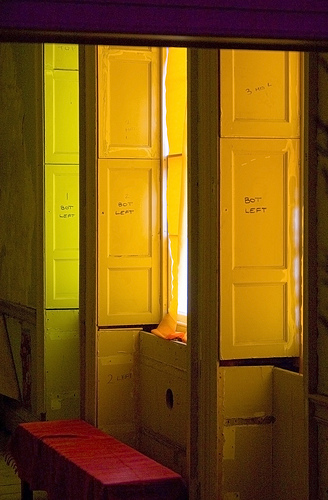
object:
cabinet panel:
[95, 155, 165, 331]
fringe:
[1, 446, 26, 477]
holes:
[222, 415, 277, 427]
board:
[217, 365, 273, 498]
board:
[96, 326, 143, 447]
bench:
[15, 418, 188, 499]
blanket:
[6, 416, 187, 498]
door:
[221, 135, 304, 358]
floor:
[1, 449, 54, 466]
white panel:
[220, 138, 303, 361]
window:
[160, 45, 188, 333]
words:
[240, 190, 270, 218]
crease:
[37, 428, 111, 443]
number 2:
[105, 371, 114, 385]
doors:
[41, 42, 81, 165]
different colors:
[87, 43, 310, 499]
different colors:
[40, 43, 82, 422]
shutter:
[96, 159, 162, 329]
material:
[149, 40, 187, 344]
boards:
[0, 452, 22, 500]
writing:
[237, 81, 277, 97]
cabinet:
[43, 163, 82, 311]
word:
[54, 197, 80, 223]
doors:
[95, 44, 161, 161]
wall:
[1, 47, 328, 499]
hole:
[163, 386, 175, 412]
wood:
[137, 330, 189, 480]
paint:
[43, 313, 82, 418]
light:
[159, 44, 188, 324]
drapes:
[150, 45, 188, 343]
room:
[0, 0, 328, 498]